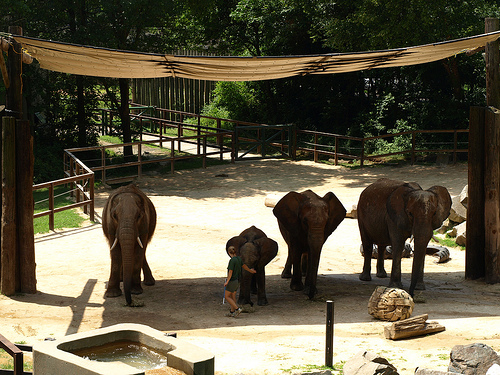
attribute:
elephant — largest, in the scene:
[348, 171, 455, 295]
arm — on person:
[220, 263, 230, 290]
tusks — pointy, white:
[106, 230, 183, 251]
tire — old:
[356, 239, 412, 260]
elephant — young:
[223, 222, 280, 308]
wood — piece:
[383, 312, 445, 342]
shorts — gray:
[221, 276, 244, 296]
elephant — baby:
[226, 224, 276, 314]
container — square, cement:
[20, 307, 188, 374]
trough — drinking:
[29, 317, 226, 373]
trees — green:
[1, 0, 499, 162]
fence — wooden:
[66, 120, 464, 180]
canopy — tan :
[4, 33, 499, 80]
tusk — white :
[137, 235, 145, 249]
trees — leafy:
[209, 12, 498, 154]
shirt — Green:
[215, 276, 240, 296]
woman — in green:
[221, 244, 261, 314]